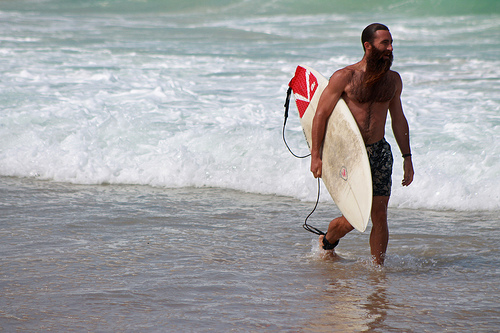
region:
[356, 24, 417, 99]
the head of a man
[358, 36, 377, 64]
the ear of a man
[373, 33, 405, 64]
the nose of a man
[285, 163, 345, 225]
the hand of a man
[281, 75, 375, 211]
the arm of a man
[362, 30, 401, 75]
the eyes of a man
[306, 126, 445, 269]
the legs of a man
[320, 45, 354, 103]
the shoulder of a man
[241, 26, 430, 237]
a man holding a snowboard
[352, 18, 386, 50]
the hair of a man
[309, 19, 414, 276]
man walking on the beach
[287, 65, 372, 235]
man carrying a white surfboard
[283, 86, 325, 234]
black wire on a surfboard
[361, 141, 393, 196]
man wearing black shorts with white flowers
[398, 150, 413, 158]
man wearing a black watch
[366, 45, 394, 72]
man with a long brown beard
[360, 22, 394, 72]
man with sort brown hair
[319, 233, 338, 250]
man wearing a black band in his ankle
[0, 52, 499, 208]
a wave washing on the beach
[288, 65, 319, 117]
red logo on a surfboard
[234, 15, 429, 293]
The man is walking in the water.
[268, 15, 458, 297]
The man is wearing a leg leash.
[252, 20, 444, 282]
The man is carrying a surfboard.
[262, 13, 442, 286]
The surfboard is red and white.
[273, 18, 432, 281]
The man has a beard.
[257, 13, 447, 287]
The man has a moustache.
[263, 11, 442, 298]
The man has a hairy chest.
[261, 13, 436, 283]
The man is shirtless.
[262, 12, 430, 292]
The man is wearing swimming trunks.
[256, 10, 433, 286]
The man is barefoot.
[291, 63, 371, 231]
A red and white surfboard.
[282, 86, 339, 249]
A long black safety cord with ankle strap.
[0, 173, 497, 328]
Silver calmer water with a man walking through it.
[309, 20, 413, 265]
A brown haired man in shorts walking through water.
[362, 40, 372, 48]
A right ear of a man walking.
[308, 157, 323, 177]
A right hand of a man walking.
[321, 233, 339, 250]
The black ankle strap on a man.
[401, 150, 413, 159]
Black bracelet on a man's left wrist.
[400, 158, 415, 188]
A man's left hand.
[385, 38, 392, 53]
Nose on a man's face.